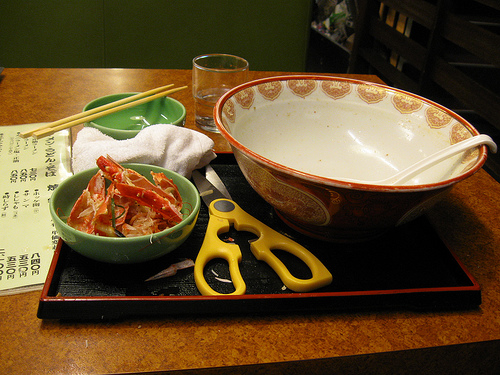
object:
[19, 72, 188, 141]
chopsticks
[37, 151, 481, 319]
plate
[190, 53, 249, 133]
cup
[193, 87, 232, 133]
water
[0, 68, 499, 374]
table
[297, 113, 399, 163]
white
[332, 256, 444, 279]
black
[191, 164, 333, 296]
scissors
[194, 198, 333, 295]
handles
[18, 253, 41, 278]
black writing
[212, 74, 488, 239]
bowl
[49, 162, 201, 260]
bowl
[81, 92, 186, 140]
bowl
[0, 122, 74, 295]
menu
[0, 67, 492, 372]
tabletop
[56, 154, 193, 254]
crab met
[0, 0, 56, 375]
left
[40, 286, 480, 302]
edge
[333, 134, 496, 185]
spoon